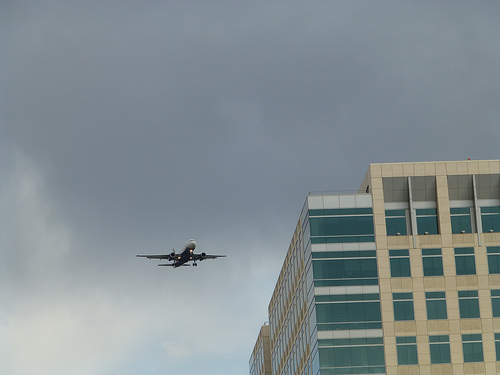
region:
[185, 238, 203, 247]
The nose of the plane.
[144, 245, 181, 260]
The left side wing of the plane.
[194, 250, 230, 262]
The right side wing of the plane.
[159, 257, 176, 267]
The left side wing on the tail.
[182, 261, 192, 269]
The right side wing on the tail.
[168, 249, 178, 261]
The left side engine on the wing.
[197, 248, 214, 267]
The right side engine on the wing.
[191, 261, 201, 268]
The wheels on the right side of the plane.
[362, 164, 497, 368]
The beige blocks of the building facing forward.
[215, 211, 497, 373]
The windows of the buildings on the right.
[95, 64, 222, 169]
gray cloud in daytime sky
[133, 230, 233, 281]
plane flying in sky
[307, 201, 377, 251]
blue windows on building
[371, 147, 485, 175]
flat roof of building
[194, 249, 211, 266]
jet engine on wing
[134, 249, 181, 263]
wing on side of plane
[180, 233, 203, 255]
nose on front of plane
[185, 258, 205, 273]
wheel on landing gear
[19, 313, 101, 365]
white cloud in sky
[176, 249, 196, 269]
bottom of flying plane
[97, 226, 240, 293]
The plane is grey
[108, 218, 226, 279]
The plane is flying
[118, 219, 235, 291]
The plane is in mid-air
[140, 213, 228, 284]
The plane has its landing gear down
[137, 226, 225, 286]
The plane has three lights underneath it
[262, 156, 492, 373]
The building has many windows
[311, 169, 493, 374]
The windows are blue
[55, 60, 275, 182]
The sky is hazy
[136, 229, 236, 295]
The plane has two engines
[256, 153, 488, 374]
The building is tall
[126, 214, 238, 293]
jet airliner in cloudy sky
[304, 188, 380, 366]
building with green windows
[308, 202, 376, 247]
horizontal row of green windows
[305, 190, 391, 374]
vertical row of green windows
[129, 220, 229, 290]
airplane with landing lights on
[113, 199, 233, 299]
jet airliner with landing gear down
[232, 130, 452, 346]
top of building and cloudy sky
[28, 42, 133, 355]
a gray cloudy sky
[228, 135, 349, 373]
two building with matching windows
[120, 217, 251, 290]
flying plane with lights on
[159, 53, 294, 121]
the sky is dark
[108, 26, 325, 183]
the sky is dark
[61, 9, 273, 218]
the sky is dark